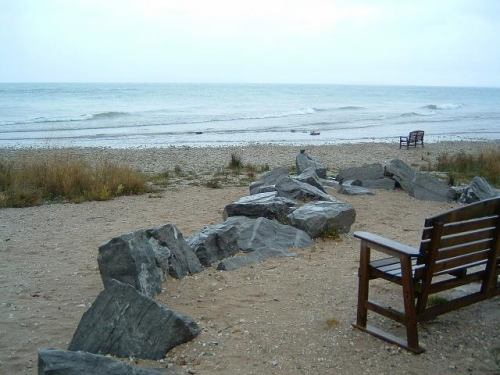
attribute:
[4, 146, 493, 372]
foreground — wood, heavy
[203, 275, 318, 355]
sand — brown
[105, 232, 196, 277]
gray rock — LARGE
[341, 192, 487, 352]
bench — WOODEN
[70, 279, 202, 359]
rock — GRAY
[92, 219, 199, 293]
rock — slate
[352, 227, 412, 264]
arm rest — wooden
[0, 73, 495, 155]
ocean — filled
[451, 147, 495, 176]
grass — SEA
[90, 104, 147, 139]
waves — calm, small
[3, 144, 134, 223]
grass — BEACH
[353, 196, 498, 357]
bench — perfectly constructed, WOODEN, brown, wood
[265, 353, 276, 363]
rock — TINY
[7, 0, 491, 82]
sky — blue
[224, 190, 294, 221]
rock — grey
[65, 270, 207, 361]
rock — tiny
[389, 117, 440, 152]
bench — overlooking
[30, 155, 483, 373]
rocks — GRAY, LARGE